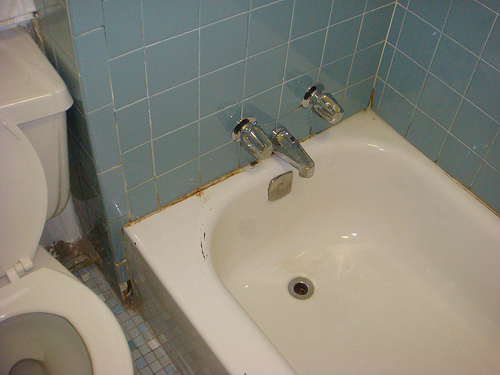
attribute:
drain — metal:
[286, 276, 314, 299]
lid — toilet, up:
[1, 111, 54, 283]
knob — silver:
[223, 117, 277, 168]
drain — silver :
[287, 274, 316, 300]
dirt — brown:
[46, 231, 97, 276]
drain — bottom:
[282, 271, 316, 301]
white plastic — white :
[5, 110, 161, 373]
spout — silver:
[270, 126, 336, 186]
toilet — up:
[2, 28, 134, 371]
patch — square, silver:
[268, 170, 290, 202]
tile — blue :
[142, 27, 201, 96]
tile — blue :
[360, 6, 395, 50]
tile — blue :
[282, 27, 328, 74]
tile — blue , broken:
[426, 31, 478, 93]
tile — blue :
[449, 96, 496, 159]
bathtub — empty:
[122, 110, 497, 372]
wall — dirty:
[29, 0, 136, 301]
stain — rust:
[123, 159, 253, 227]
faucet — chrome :
[267, 125, 315, 177]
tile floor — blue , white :
[105, 277, 168, 371]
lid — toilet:
[2, 120, 48, 275]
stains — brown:
[55, 237, 158, 313]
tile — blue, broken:
[143, 32, 200, 94]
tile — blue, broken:
[191, 66, 246, 110]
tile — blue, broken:
[132, 338, 146, 349]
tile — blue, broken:
[280, 35, 335, 74]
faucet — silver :
[269, 124, 316, 179]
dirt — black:
[197, 229, 210, 260]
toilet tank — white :
[3, 40, 77, 221]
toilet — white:
[0, 37, 152, 373]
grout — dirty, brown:
[175, 181, 211, 217]